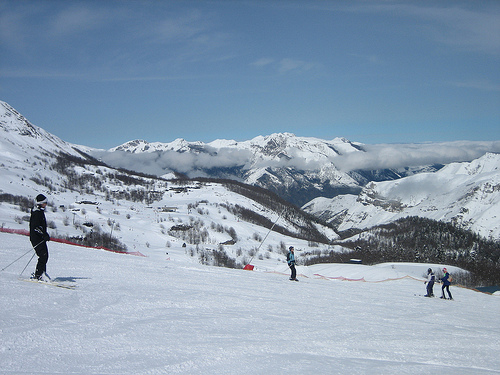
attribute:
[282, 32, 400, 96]
sky — blue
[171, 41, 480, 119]
clouds — white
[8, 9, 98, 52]
cloud — White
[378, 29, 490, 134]
sky — Blue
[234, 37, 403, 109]
sky — blue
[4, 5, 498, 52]
clouds — white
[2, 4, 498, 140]
sky — Blue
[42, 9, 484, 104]
clouds — white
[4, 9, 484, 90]
clouds — white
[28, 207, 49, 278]
skiing — black